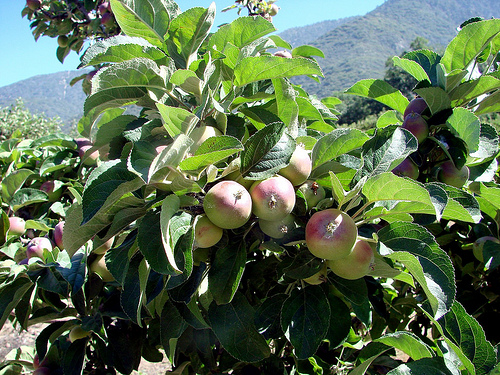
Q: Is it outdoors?
A: Yes, it is outdoors.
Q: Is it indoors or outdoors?
A: It is outdoors.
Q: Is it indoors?
A: No, it is outdoors.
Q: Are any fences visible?
A: No, there are no fences.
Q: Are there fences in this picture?
A: No, there are no fences.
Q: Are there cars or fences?
A: No, there are no fences or cars.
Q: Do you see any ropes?
A: No, there are no ropes.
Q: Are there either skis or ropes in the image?
A: No, there are no ropes or skis.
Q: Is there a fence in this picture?
A: No, there are no fences.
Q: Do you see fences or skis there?
A: No, there are no fences or skis.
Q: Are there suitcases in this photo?
A: No, there are no suitcases.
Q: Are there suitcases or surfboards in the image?
A: No, there are no suitcases or surfboards.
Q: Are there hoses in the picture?
A: No, there are no hoses.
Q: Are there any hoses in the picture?
A: No, there are no hoses.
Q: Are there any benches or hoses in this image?
A: No, there are no hoses or benches.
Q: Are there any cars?
A: No, there are no cars.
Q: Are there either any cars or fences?
A: No, there are no cars or fences.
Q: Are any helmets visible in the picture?
A: No, there are no helmets.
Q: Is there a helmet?
A: No, there are no helmets.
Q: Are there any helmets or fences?
A: No, there are no helmets or fences.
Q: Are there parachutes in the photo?
A: No, there are no parachutes.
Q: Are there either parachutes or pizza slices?
A: No, there are no parachutes or pizza slices.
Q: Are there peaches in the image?
A: Yes, there is a peach.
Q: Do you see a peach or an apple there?
A: Yes, there is a peach.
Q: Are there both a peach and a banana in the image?
A: No, there is a peach but no bananas.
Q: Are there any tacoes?
A: No, there are no tacoes.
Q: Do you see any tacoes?
A: No, there are no tacoes.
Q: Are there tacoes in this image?
A: No, there are no tacoes.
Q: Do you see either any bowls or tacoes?
A: No, there are no tacoes or bowls.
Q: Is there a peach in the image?
A: Yes, there is a peach.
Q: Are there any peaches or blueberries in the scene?
A: Yes, there is a peach.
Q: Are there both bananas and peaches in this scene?
A: No, there is a peach but no bananas.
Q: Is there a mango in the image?
A: No, there are no mangoes.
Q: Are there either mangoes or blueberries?
A: No, there are no mangoes or blueberries.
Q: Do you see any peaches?
A: Yes, there is a peach.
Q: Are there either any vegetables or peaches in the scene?
A: Yes, there is a peach.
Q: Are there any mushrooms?
A: No, there are no mushrooms.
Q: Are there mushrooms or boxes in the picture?
A: No, there are no mushrooms or boxes.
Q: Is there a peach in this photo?
A: Yes, there is a peach.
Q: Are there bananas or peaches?
A: Yes, there is a peach.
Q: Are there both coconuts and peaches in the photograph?
A: No, there is a peach but no coconuts.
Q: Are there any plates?
A: No, there are no plates.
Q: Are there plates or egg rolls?
A: No, there are no plates or egg rolls.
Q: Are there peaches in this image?
A: Yes, there is a peach.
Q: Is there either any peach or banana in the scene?
A: Yes, there is a peach.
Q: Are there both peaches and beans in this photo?
A: No, there is a peach but no beans.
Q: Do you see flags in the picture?
A: No, there are no flags.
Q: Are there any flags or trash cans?
A: No, there are no flags or trash cans.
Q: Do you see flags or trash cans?
A: No, there are no flags or trash cans.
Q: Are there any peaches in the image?
A: Yes, there is a peach.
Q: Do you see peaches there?
A: Yes, there is a peach.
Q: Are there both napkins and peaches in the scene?
A: No, there is a peach but no napkins.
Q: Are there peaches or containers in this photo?
A: Yes, there is a peach.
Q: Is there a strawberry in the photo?
A: No, there are no strawberries.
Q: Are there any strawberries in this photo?
A: No, there are no strawberries.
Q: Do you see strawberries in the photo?
A: No, there are no strawberries.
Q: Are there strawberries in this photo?
A: No, there are no strawberries.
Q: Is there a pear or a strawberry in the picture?
A: No, there are no strawberries or pears.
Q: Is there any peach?
A: Yes, there is a peach.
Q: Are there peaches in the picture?
A: Yes, there is a peach.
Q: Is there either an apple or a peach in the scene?
A: Yes, there is a peach.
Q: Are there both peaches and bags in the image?
A: No, there is a peach but no bags.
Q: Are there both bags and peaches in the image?
A: No, there is a peach but no bags.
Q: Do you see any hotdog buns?
A: No, there are no hotdog buns.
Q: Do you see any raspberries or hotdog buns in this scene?
A: No, there are no hotdog buns or raspberries.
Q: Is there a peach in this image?
A: Yes, there is a peach.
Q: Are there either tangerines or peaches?
A: Yes, there is a peach.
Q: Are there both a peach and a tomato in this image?
A: No, there is a peach but no tomatoes.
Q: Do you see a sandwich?
A: No, there are no sandwiches.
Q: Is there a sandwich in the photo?
A: No, there are no sandwiches.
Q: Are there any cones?
A: No, there are no cones.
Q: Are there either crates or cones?
A: No, there are no cones or crates.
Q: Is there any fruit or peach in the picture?
A: Yes, there is a peach.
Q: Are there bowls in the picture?
A: No, there are no bowls.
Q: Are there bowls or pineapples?
A: No, there are no bowls or pineapples.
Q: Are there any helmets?
A: No, there are no helmets.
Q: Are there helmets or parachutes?
A: No, there are no helmets or parachutes.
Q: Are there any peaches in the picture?
A: Yes, there is a peach.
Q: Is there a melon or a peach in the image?
A: Yes, there is a peach.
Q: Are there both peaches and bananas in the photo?
A: No, there is a peach but no bananas.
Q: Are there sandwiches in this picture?
A: No, there are no sandwiches.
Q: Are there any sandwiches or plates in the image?
A: No, there are no sandwiches or plates.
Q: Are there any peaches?
A: Yes, there is a peach.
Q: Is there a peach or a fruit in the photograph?
A: Yes, there is a peach.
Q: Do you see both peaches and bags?
A: No, there is a peach but no bags.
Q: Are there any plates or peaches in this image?
A: Yes, there is a peach.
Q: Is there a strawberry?
A: No, there are no strawberries.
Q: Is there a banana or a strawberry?
A: No, there are no strawberries or bananas.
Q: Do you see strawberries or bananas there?
A: No, there are no strawberries or bananas.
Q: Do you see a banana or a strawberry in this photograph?
A: No, there are no strawberries or bananas.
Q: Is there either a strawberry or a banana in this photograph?
A: No, there are no strawberries or bananas.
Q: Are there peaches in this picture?
A: Yes, there is a peach.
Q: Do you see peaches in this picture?
A: Yes, there is a peach.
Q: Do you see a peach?
A: Yes, there is a peach.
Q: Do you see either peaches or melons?
A: Yes, there is a peach.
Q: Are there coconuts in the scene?
A: No, there are no coconuts.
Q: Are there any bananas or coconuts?
A: No, there are no coconuts or bananas.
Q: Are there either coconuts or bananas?
A: No, there are no coconuts or bananas.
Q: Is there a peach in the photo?
A: Yes, there is a peach.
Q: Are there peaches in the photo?
A: Yes, there is a peach.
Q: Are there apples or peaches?
A: Yes, there is a peach.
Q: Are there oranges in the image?
A: No, there are no oranges.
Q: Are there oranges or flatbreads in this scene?
A: No, there are no oranges or flatbreads.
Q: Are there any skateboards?
A: No, there are no skateboards.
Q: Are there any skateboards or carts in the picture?
A: No, there are no skateboards or carts.